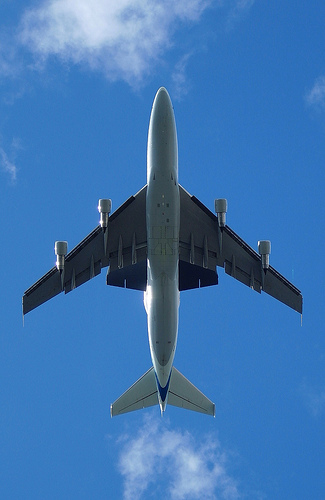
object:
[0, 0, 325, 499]
blue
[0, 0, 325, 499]
sky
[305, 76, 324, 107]
clouds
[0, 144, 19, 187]
clouds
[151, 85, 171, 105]
nose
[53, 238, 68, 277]
engine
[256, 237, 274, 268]
engine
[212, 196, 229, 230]
engine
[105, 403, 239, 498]
clouds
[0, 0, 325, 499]
no birds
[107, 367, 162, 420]
tail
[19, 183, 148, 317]
tail wing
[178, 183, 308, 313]
wing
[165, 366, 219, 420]
tail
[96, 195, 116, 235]
engine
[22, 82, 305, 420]
airplane